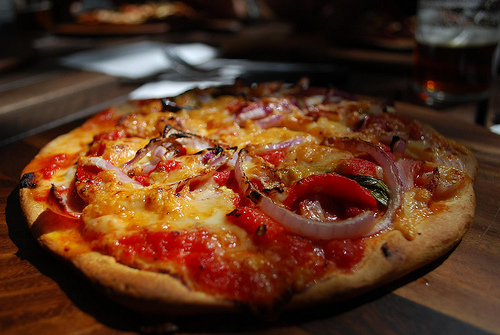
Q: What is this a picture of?
A: Pizza.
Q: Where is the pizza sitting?
A: Table.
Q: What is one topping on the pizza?
A: Onion.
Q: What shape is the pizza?
A: Circle.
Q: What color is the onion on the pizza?
A: Purple.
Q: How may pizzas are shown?
A: One.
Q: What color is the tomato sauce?
A: Red.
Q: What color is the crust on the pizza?
A: Brown.